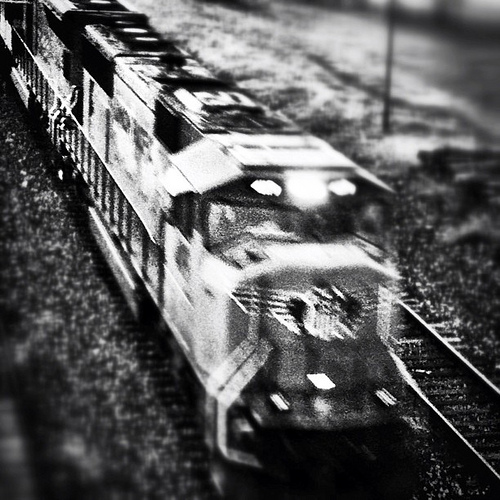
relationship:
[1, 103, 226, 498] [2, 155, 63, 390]
gravel next to train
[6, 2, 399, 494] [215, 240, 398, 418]
train has a front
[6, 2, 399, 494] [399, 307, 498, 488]
train on tracks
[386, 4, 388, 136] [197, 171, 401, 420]
post by train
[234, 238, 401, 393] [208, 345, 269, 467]
engine has a bar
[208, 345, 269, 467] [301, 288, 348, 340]
engine has a logo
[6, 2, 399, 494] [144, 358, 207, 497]
train running on tracks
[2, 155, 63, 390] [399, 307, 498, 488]
gravel on side of tracks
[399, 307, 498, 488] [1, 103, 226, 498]
tracks are on side of gravel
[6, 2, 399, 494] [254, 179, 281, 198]
train has lights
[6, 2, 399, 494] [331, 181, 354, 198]
train has lights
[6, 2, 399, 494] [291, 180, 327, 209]
train has light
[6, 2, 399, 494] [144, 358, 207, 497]
train running on rail road tracks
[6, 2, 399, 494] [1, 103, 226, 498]
train running through gravel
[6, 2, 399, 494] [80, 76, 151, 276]
train has a side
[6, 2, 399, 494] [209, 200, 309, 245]
train has a window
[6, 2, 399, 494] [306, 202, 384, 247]
train has a window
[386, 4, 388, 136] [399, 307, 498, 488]
post on side of tracks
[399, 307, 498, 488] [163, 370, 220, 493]
railroad has a track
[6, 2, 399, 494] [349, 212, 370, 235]
train has a engineer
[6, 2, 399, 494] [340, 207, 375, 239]
train has a engineer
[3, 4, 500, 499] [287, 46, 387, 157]
picture has a lot of noise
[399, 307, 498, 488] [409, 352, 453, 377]
tracks are made of wood planks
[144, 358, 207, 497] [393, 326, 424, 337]
tracks are made of wood planks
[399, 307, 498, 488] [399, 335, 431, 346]
tracks are made of wood planks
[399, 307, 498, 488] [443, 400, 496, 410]
tracks are made of wood planks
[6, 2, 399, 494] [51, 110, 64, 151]
train has metal bars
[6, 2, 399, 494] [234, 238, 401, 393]
train has a engine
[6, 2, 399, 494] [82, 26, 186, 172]
train has a car